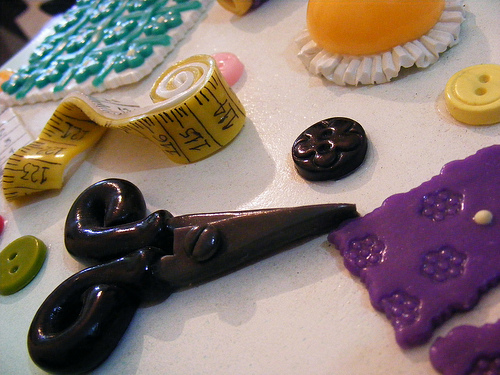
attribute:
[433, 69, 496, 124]
button — yellow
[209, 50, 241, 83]
button — pink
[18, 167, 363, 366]
scissor — black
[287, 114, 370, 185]
circle — black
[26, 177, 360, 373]
scissors — black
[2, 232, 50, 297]
button — green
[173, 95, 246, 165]
numbers — white, black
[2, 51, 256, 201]
measuring tape — yellow